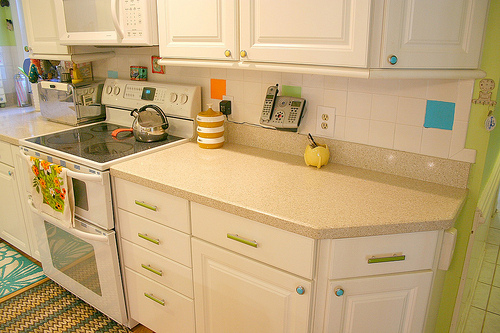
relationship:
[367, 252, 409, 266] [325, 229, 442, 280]
green handle on drawer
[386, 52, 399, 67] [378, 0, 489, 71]
blue knob on cupboard door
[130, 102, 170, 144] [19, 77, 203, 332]
tea kettle on stove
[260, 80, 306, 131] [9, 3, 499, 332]
telephone on wall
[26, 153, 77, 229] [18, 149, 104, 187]
towel on oven door handle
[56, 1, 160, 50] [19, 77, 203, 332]
microwave over stove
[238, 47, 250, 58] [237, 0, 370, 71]
yellow knob on cupboard door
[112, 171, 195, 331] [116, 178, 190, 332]
cabinet with drawers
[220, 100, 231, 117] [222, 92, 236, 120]
phone plug in outlet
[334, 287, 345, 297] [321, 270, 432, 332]
blue knob on cabinet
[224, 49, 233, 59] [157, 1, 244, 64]
yellow knob on cabinet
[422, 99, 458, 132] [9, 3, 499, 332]
blue paper on wall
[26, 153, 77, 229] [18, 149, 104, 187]
towel hanging from oven door handle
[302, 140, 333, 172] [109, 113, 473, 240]
yellow vase on countertop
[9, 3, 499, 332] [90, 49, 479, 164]
wall has tile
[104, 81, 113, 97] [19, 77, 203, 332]
white knob on stove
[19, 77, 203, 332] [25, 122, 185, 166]
stove has black top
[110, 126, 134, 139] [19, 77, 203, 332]
spoon rest on stove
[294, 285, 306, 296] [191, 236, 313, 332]
blue knob on cabinet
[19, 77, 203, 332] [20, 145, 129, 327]
stove has two doors